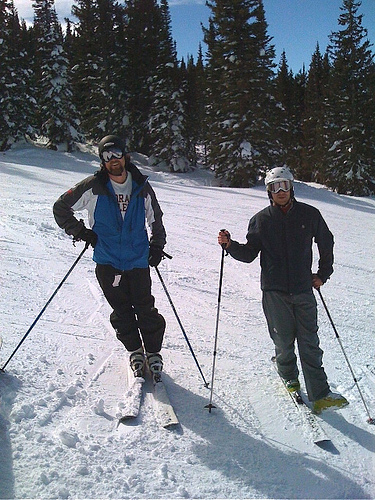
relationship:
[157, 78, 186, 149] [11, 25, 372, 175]
snow on trees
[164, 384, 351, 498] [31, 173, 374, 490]
shadow on ground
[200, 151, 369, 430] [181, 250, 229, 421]
man holds pole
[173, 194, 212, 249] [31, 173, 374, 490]
snow on ground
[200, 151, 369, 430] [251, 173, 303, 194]
man wears goggles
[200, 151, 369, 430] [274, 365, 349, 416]
man wears boots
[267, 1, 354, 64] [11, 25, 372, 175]
sky behind trees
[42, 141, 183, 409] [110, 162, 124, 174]
man has hair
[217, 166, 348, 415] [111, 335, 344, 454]
man have skis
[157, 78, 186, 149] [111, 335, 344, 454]
snow on skis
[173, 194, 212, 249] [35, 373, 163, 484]
snow has tracks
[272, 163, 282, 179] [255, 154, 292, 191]
holes in helmet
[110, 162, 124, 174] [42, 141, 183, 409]
hair on man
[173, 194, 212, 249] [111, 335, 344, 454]
snow on skis